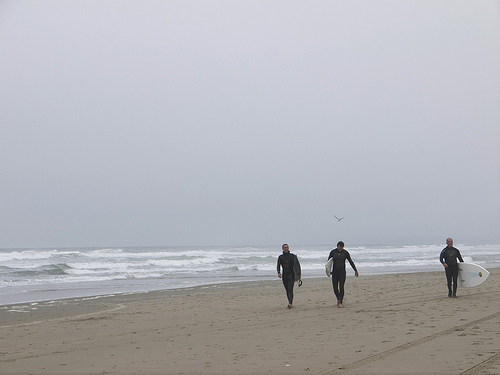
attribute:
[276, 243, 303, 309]
surfer — walking, friend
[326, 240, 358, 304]
surfer — walking, friend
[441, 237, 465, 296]
surfer — walking, friend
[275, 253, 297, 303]
wet suit — black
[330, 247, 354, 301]
wet suit — black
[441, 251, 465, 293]
wet suit — black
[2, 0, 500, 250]
sky — overcast, grey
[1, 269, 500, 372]
beach — wet, sandy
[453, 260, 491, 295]
surf board — white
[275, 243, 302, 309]
surfers — barefoot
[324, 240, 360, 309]
surfers — barefoot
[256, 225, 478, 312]
wetssuits — black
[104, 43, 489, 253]
sky — grey, cloudy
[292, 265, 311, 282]
surfboard — held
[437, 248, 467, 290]
wetsuit — black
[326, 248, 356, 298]
wetsuit — black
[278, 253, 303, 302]
wetsuit — black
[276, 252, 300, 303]
wetsuits — black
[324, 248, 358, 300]
wetsuits — black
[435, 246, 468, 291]
wetsuits — black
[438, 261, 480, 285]
surfboard — white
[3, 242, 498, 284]
waves — white, cresting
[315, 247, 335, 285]
surfboards — white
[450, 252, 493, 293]
surfboards — white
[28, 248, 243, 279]
ocean — choppy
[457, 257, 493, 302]
surfboard — white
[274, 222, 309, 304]
suit — black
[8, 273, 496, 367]
sand — wet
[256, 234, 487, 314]
surfwear — black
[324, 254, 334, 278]
surfboard — white